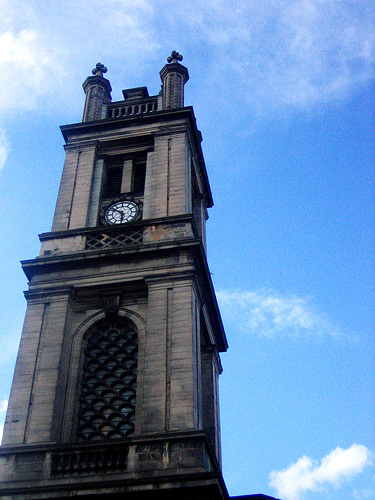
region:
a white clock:
[100, 195, 142, 229]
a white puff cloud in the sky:
[269, 437, 365, 498]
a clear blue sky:
[259, 173, 371, 259]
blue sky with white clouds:
[207, 0, 372, 135]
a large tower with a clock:
[0, 52, 226, 496]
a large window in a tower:
[67, 307, 145, 442]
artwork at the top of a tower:
[162, 48, 183, 67]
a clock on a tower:
[97, 195, 149, 229]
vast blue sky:
[234, 163, 371, 249]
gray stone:
[170, 362, 197, 374]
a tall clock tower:
[0, 50, 281, 499]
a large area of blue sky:
[0, 0, 373, 499]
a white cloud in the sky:
[267, 442, 373, 498]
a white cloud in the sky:
[214, 284, 359, 346]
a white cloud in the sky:
[0, 398, 9, 414]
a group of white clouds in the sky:
[0, 0, 374, 133]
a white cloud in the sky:
[0, 126, 13, 171]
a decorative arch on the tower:
[59, 306, 146, 443]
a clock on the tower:
[103, 199, 138, 225]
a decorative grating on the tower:
[83, 225, 143, 250]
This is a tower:
[3, 36, 234, 498]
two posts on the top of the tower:
[69, 41, 230, 131]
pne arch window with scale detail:
[58, 311, 151, 455]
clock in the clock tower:
[102, 198, 148, 231]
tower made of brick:
[121, 167, 220, 470]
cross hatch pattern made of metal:
[77, 224, 172, 263]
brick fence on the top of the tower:
[102, 93, 178, 130]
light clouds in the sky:
[255, 425, 369, 491]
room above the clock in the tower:
[84, 143, 171, 221]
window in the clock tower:
[181, 154, 207, 248]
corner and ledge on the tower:
[159, 207, 214, 317]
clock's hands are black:
[97, 194, 161, 242]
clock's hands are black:
[96, 185, 137, 232]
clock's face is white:
[93, 172, 140, 229]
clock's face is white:
[97, 179, 153, 249]